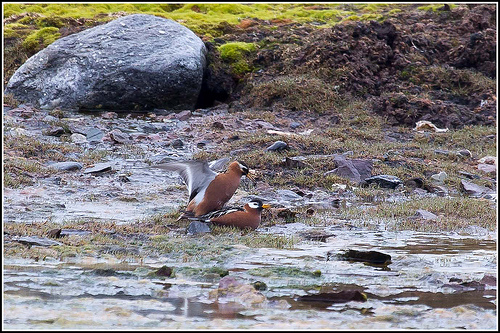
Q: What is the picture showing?
A: It is showing a beach.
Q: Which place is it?
A: It is a beach.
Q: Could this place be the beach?
A: Yes, it is the beach.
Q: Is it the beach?
A: Yes, it is the beach.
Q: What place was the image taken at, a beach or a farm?
A: It was taken at a beach.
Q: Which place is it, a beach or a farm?
A: It is a beach.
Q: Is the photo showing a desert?
A: No, the picture is showing a beach.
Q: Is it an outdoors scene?
A: Yes, it is outdoors.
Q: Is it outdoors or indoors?
A: It is outdoors.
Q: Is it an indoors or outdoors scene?
A: It is outdoors.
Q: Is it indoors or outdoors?
A: It is outdoors.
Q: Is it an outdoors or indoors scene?
A: It is outdoors.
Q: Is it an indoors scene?
A: No, it is outdoors.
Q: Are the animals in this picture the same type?
A: Yes, all the animals are birds.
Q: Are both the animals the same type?
A: Yes, all the animals are birds.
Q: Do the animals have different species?
A: No, all the animals are birds.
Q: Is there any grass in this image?
A: Yes, there is grass.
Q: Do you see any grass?
A: Yes, there is grass.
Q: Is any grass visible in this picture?
A: Yes, there is grass.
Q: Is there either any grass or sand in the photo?
A: Yes, there is grass.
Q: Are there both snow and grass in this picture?
A: No, there is grass but no snow.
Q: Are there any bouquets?
A: No, there are no bouquets.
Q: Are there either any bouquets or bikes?
A: No, there are no bouquets or bikes.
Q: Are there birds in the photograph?
A: Yes, there is a bird.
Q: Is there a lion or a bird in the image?
A: Yes, there is a bird.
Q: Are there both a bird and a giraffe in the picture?
A: No, there is a bird but no giraffes.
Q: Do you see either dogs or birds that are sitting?
A: Yes, the bird is sitting.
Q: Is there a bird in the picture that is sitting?
A: Yes, there is a bird that is sitting.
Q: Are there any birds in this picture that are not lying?
A: Yes, there is a bird that is sitting.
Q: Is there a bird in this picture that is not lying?
A: Yes, there is a bird that is sitting.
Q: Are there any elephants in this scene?
A: No, there are no elephants.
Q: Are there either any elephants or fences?
A: No, there are no elephants or fences.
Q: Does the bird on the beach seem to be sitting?
A: Yes, the bird is sitting.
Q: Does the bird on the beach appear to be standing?
A: No, the bird is sitting.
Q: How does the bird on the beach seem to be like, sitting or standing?
A: The bird is sitting.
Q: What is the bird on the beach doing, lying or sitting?
A: The bird is sitting.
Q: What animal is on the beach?
A: The animal is a bird.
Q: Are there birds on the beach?
A: Yes, there is a bird on the beach.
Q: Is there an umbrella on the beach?
A: No, there is a bird on the beach.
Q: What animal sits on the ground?
A: The bird sits on the ground.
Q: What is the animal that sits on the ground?
A: The animal is a bird.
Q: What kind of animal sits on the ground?
A: The animal is a bird.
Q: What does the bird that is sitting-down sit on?
A: The bird sits on the ground.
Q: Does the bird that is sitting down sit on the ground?
A: Yes, the bird sits on the ground.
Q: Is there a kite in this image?
A: No, there are no kites.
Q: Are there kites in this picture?
A: No, there are no kites.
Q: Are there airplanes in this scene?
A: No, there are no airplanes.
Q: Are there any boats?
A: No, there are no boats.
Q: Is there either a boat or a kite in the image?
A: No, there are no boats or kites.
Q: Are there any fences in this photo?
A: No, there are no fences.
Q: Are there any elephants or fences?
A: No, there are no fences or elephants.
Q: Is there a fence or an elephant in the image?
A: No, there are no fences or elephants.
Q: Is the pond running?
A: Yes, the pond is running.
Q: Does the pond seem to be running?
A: Yes, the pond is running.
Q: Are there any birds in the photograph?
A: Yes, there is a bird.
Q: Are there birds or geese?
A: Yes, there is a bird.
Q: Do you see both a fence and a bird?
A: No, there is a bird but no fences.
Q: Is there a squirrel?
A: No, there are no squirrels.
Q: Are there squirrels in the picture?
A: No, there are no squirrels.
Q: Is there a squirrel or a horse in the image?
A: No, there are no squirrels or horses.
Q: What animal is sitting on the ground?
A: The bird is sitting on the ground.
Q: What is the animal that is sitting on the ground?
A: The animal is a bird.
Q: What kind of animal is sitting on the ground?
A: The animal is a bird.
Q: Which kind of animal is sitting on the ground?
A: The animal is a bird.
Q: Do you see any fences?
A: No, there are no fences.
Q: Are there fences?
A: No, there are no fences.